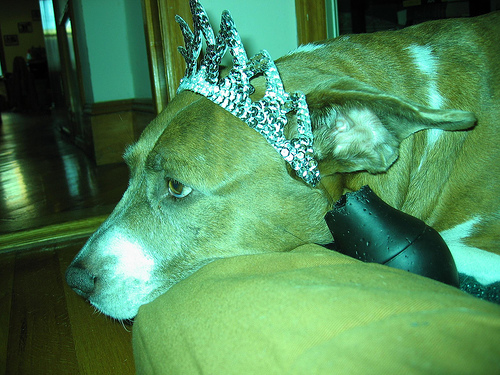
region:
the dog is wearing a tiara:
[103, 16, 380, 305]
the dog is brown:
[74, 86, 354, 326]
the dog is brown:
[81, 13, 482, 353]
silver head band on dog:
[149, 16, 341, 216]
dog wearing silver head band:
[164, 29, 326, 187]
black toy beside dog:
[329, 171, 453, 280]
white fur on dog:
[76, 242, 178, 317]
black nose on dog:
[67, 253, 99, 315]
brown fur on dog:
[171, 138, 302, 236]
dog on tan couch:
[231, 115, 428, 366]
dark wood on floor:
[11, 261, 139, 368]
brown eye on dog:
[161, 168, 191, 200]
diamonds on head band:
[256, 114, 335, 176]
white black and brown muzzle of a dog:
[59, 223, 191, 324]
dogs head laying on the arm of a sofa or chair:
[55, 62, 360, 318]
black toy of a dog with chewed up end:
[324, 182, 475, 294]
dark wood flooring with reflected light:
[0, 104, 119, 211]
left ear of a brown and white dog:
[299, 75, 494, 181]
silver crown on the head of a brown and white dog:
[165, 2, 329, 193]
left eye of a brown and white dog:
[156, 171, 195, 209]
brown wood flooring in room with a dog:
[9, 212, 137, 367]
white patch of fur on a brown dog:
[433, 215, 494, 290]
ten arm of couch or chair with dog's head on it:
[110, 244, 488, 366]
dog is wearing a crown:
[28, 0, 339, 262]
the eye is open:
[113, 147, 222, 216]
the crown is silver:
[155, 0, 340, 196]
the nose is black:
[35, 240, 106, 298]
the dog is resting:
[14, 0, 459, 344]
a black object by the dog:
[278, 167, 467, 280]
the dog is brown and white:
[50, 18, 490, 321]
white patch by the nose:
[93, 217, 169, 303]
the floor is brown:
[0, 252, 135, 364]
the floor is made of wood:
[1, 225, 123, 362]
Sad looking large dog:
[69, 13, 498, 320]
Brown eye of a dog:
[161, 175, 194, 201]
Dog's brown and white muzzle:
[63, 203, 206, 320]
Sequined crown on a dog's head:
[64, 0, 330, 319]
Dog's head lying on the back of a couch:
[63, 65, 499, 373]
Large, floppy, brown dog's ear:
[298, 76, 475, 185]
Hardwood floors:
[0, 105, 151, 372]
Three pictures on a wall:
[1, 5, 41, 47]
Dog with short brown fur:
[71, 18, 498, 320]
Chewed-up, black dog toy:
[324, 185, 461, 285]